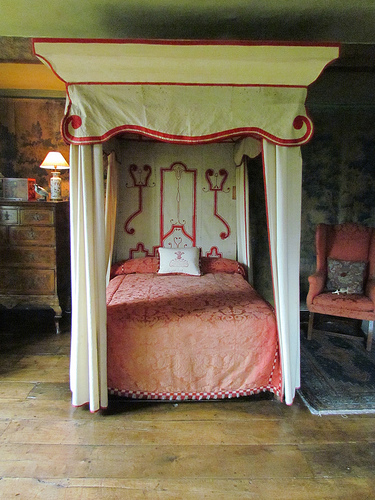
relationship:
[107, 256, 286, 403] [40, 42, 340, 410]
blanket on bed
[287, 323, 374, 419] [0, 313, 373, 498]
rug on floor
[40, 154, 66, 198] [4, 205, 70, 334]
lamp on dresser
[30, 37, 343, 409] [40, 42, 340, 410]
canopy over bed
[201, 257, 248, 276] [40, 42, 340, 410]
pillow on bed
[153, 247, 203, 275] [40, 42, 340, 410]
pillow on bed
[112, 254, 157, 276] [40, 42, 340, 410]
pillow on bed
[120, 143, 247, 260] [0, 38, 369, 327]
decoration on wall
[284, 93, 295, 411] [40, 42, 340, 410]
post on bed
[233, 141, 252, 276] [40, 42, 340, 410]
post on bed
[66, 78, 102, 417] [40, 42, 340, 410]
post on bed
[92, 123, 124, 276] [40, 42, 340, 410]
post on bed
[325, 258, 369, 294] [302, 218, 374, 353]
pillow on chair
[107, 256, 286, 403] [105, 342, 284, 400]
blanket has fringe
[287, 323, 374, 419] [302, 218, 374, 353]
rug under chair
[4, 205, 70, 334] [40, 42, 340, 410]
dresser beside bed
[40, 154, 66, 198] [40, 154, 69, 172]
lamp has shade